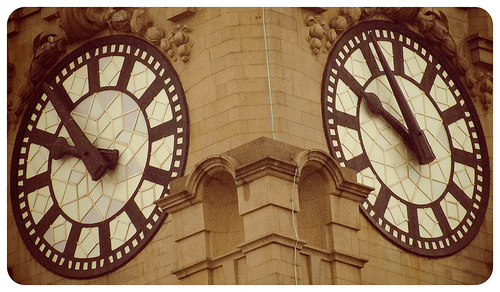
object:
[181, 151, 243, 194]
arch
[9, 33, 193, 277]
clock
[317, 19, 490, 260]
clock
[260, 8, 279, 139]
cable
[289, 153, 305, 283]
cable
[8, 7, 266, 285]
wall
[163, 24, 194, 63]
decorations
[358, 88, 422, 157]
hour hand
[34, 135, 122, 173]
hour hand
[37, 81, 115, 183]
hands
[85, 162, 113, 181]
lower end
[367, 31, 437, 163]
minute hand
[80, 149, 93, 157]
pin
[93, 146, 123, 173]
end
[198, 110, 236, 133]
bricks